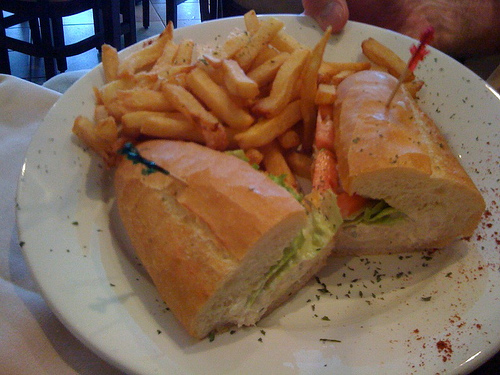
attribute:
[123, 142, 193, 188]
toothpick — blue , plastic 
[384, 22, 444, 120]
toothpick — plastic , red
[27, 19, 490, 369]
plate — round , white 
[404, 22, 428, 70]
tag — red 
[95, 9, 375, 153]
french fries — Golden 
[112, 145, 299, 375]
bread — white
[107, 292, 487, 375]
plate — white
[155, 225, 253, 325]
bread — white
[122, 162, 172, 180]
toothpick — blue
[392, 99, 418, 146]
toothpick — red